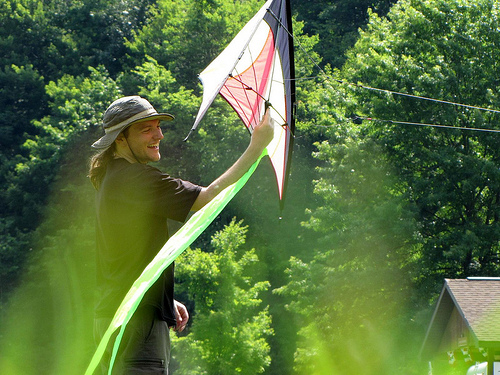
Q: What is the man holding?
A: Kite.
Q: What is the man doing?
A: Smiling.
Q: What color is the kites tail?
A: Green and white.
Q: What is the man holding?
A: Kite.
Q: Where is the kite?
A: In the man's hand.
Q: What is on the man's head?
A: Hat.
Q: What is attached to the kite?
A: Strings.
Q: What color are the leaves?
A: Green.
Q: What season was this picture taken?
A: Summer.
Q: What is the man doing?
A: Holding a kite.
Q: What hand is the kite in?
A: Right.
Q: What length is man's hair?
A: Long.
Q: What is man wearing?
A: Hat.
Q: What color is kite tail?
A: Green.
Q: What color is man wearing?
A: Black.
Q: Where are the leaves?
A: On trees.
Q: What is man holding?
A: Kite.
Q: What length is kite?
A: Long.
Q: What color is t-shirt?
A: Black.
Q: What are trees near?
A: Building.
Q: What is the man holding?
A: A kite.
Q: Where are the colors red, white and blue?
A: On the kite.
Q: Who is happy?
A: The man.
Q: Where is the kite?
A: In the man's hand.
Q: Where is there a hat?
A: On the man's head.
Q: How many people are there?
A: One.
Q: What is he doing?
A: Holding a kite.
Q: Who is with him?
A: No one.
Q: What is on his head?
A: A hat.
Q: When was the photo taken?
A: Daytime.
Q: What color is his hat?
A: Gray.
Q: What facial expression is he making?
A: Smiling.